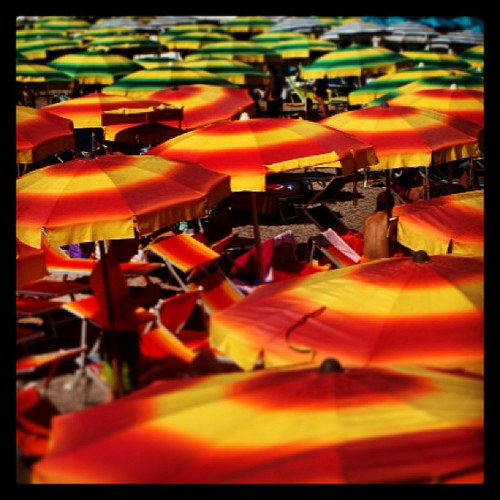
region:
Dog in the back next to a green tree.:
[436, 476, 465, 480]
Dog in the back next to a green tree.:
[208, 353, 209, 486]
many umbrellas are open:
[137, 7, 422, 187]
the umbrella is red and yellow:
[0, 134, 252, 213]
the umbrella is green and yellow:
[298, 33, 385, 88]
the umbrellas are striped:
[314, 12, 427, 44]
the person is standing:
[336, 175, 403, 262]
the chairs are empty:
[288, 188, 367, 265]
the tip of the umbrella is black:
[307, 350, 349, 375]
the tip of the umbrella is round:
[291, 339, 357, 384]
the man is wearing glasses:
[95, 225, 145, 268]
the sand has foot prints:
[330, 192, 367, 225]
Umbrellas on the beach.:
[41, 57, 467, 471]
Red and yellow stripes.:
[210, 199, 434, 371]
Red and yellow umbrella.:
[251, 210, 461, 420]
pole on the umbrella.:
[233, 147, 318, 302]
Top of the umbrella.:
[296, 331, 398, 419]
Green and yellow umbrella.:
[101, 33, 288, 95]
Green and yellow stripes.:
[63, 42, 284, 89]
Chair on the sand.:
[268, 157, 369, 243]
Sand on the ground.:
[236, 158, 389, 287]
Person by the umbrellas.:
[349, 163, 419, 307]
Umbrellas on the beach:
[67, 52, 434, 399]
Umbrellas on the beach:
[107, 173, 307, 368]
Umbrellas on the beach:
[243, 317, 442, 496]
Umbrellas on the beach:
[177, 40, 398, 146]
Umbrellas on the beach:
[283, 99, 493, 316]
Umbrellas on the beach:
[81, 30, 338, 131]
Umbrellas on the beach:
[61, 104, 326, 291]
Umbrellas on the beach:
[261, 16, 486, 116]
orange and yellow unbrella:
[13, 133, 233, 261]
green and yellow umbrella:
[297, 35, 410, 83]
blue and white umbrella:
[382, 15, 444, 45]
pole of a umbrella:
[89, 236, 115, 295]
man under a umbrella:
[68, 212, 183, 385]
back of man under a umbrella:
[354, 185, 405, 275]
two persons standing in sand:
[242, 43, 342, 125]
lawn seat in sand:
[293, 191, 363, 267]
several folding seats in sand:
[62, 240, 235, 357]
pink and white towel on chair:
[241, 223, 301, 281]